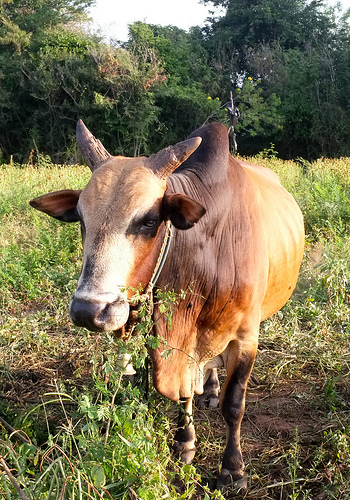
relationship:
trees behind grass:
[135, 25, 326, 123] [302, 172, 339, 219]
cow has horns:
[23, 123, 307, 469] [63, 122, 199, 178]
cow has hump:
[23, 123, 307, 469] [177, 127, 265, 176]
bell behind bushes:
[111, 348, 149, 386] [54, 394, 150, 470]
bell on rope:
[111, 348, 149, 386] [140, 252, 172, 270]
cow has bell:
[23, 123, 307, 469] [111, 348, 149, 386]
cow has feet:
[23, 123, 307, 469] [168, 409, 264, 493]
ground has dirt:
[260, 328, 347, 457] [261, 402, 290, 424]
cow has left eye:
[23, 123, 307, 469] [130, 216, 156, 234]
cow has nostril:
[23, 123, 307, 469] [93, 308, 109, 323]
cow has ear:
[23, 123, 307, 469] [154, 196, 210, 239]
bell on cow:
[111, 348, 149, 386] [23, 123, 307, 469]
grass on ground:
[302, 172, 339, 219] [260, 328, 347, 457]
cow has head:
[23, 123, 307, 469] [27, 142, 163, 311]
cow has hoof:
[23, 123, 307, 469] [227, 468, 260, 497]